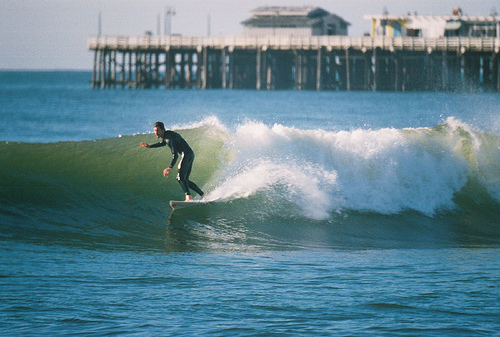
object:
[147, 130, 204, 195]
wetsuit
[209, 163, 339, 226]
water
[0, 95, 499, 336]
ocean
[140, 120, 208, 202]
man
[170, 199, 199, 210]
surfboard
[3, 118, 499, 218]
wave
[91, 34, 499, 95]
pier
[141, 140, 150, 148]
hand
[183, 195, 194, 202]
foot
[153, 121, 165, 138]
head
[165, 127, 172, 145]
shoulder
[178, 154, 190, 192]
leg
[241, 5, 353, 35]
house